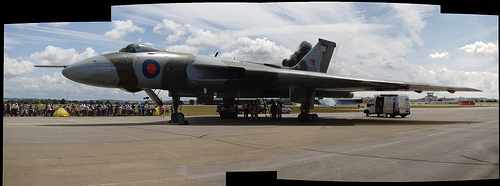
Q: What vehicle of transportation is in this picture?
A: An airplane.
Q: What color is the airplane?
A: Gray and white.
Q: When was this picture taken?
A: Daytime.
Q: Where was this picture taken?
A: An airport.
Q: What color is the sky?
A: Blue.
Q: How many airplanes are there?
A: One.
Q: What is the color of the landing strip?
A: Brown.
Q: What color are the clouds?
A: White.